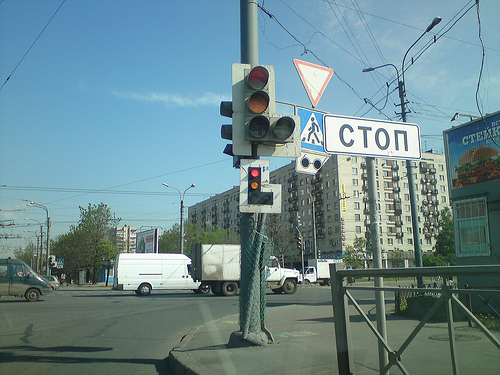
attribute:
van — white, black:
[111, 245, 213, 300]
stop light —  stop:
[238, 157, 283, 213]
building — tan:
[189, 149, 449, 264]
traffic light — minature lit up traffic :
[232, 157, 287, 219]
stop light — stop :
[236, 65, 302, 156]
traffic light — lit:
[243, 67, 271, 145]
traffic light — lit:
[274, 112, 297, 140]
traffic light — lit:
[246, 163, 263, 205]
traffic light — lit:
[218, 95, 240, 163]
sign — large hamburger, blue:
[441, 110, 498, 197]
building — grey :
[453, 186, 498, 316]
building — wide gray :
[183, 149, 451, 281]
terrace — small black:
[291, 205, 299, 217]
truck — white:
[192, 238, 304, 290]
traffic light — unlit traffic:
[243, 65, 297, 142]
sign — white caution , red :
[291, 57, 333, 109]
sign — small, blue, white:
[293, 105, 330, 155]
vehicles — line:
[2, 237, 349, 304]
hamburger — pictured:
[453, 132, 495, 200]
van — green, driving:
[0, 257, 52, 299]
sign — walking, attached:
[292, 104, 334, 155]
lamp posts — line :
[13, 180, 69, 270]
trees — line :
[47, 170, 122, 290]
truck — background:
[302, 258, 346, 285]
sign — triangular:
[292, 58, 334, 173]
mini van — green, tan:
[3, 252, 56, 302]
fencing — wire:
[232, 218, 282, 347]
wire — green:
[236, 221, 276, 336]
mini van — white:
[114, 249, 208, 299]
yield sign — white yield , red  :
[293, 57, 335, 107]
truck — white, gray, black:
[198, 234, 300, 296]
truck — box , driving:
[193, 237, 295, 289]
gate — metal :
[323, 258, 496, 373]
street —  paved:
[1, 278, 445, 373]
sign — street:
[273, 42, 360, 157]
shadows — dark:
[7, 317, 120, 364]